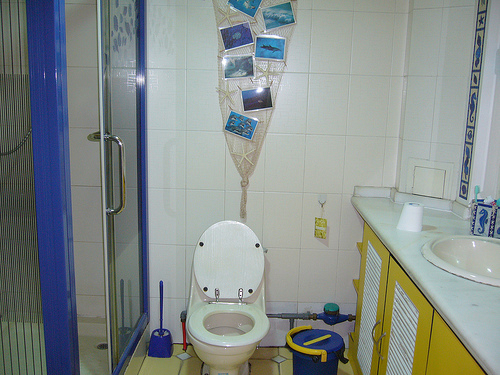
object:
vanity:
[347, 184, 500, 375]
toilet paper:
[394, 200, 427, 234]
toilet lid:
[190, 218, 268, 300]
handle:
[100, 132, 129, 217]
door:
[97, 0, 152, 374]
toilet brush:
[146, 280, 175, 358]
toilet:
[183, 217, 273, 374]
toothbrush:
[472, 184, 484, 202]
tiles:
[302, 73, 349, 136]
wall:
[144, 0, 407, 345]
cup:
[467, 200, 500, 240]